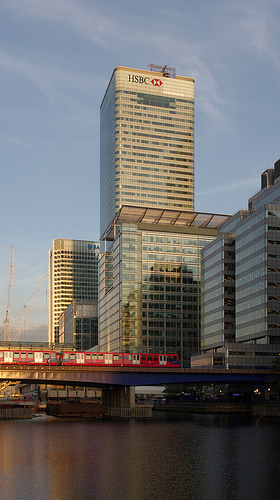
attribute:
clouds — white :
[20, 77, 47, 118]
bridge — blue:
[1, 363, 278, 387]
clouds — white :
[69, 18, 269, 61]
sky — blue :
[3, 8, 273, 210]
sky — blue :
[0, 3, 273, 244]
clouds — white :
[7, 139, 38, 151]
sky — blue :
[5, 166, 54, 227]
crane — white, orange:
[4, 269, 49, 339]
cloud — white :
[197, 97, 234, 119]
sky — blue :
[1, 2, 277, 161]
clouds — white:
[104, 18, 218, 52]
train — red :
[4, 345, 170, 362]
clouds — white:
[201, 28, 237, 62]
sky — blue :
[18, 10, 264, 196]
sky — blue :
[1, 0, 279, 69]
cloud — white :
[198, 74, 230, 121]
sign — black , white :
[126, 70, 167, 90]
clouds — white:
[0, 0, 279, 342]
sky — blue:
[1, 1, 271, 338]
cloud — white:
[2, 52, 110, 107]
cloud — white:
[2, 1, 241, 142]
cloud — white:
[210, 3, 271, 65]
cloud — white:
[3, 239, 49, 293]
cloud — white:
[1, 292, 48, 316]